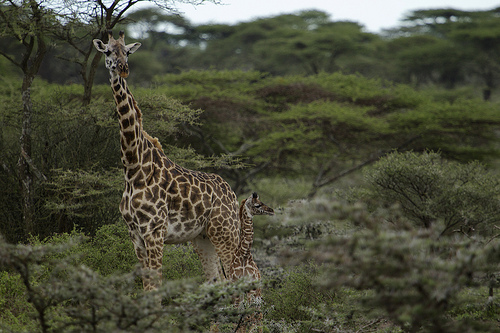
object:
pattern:
[156, 166, 174, 192]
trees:
[235, 79, 497, 204]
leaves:
[306, 75, 336, 95]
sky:
[175, 7, 405, 62]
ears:
[126, 40, 142, 56]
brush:
[332, 155, 500, 255]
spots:
[154, 179, 228, 228]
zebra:
[90, 34, 261, 333]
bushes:
[283, 193, 497, 331]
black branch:
[315, 161, 368, 189]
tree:
[239, 4, 433, 198]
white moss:
[313, 194, 330, 204]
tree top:
[291, 226, 442, 276]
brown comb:
[244, 224, 250, 231]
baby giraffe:
[224, 190, 277, 311]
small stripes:
[246, 202, 254, 226]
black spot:
[91, 40, 107, 50]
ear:
[89, 39, 111, 56]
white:
[196, 238, 212, 253]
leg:
[195, 223, 238, 310]